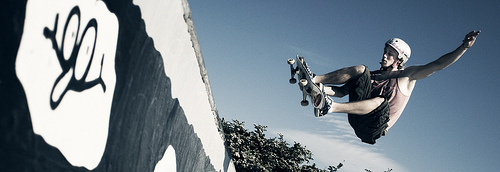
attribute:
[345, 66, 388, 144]
shorts — dark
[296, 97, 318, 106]
wheel — tan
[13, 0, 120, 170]
painted face — black and white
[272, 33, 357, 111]
shoes — white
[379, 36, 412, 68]
helmet — white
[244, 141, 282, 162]
leaves — green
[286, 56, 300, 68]
wheel — white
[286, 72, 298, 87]
wheel — white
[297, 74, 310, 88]
wheel — white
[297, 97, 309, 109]
wheel — white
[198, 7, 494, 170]
sky — blue, clear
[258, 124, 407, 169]
cloud — thin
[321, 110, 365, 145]
cloud — thin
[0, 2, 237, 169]
wall — black and white